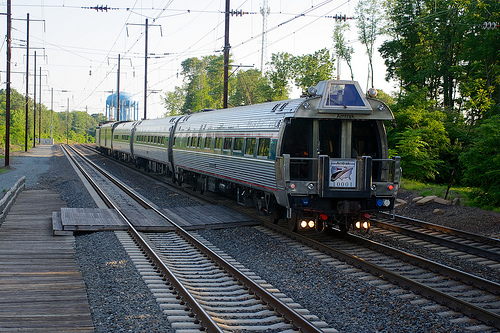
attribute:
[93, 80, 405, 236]
train — here, moving, metallic, silver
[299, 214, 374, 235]
lights — on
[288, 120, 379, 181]
door — open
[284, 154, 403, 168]
rails — here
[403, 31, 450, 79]
leaves — here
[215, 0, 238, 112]
pole — here, straight, thick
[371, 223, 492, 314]
tracks — metal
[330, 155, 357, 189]
sign — white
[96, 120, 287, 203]
four cars — red, silver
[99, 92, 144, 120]
water tower — blue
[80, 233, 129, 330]
rocks — beige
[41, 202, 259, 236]
board — wooden